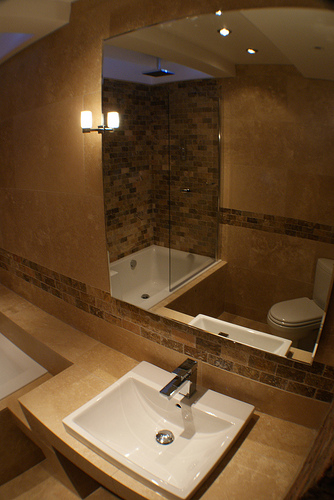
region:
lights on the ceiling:
[184, 12, 271, 68]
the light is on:
[54, 88, 143, 146]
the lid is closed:
[257, 277, 317, 337]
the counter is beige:
[233, 417, 285, 485]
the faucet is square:
[142, 344, 208, 419]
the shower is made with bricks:
[110, 83, 221, 250]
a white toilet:
[264, 254, 332, 344]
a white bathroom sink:
[62, 359, 260, 498]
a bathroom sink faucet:
[153, 354, 201, 406]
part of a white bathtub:
[106, 237, 203, 311]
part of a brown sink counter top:
[207, 410, 310, 498]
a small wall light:
[78, 105, 97, 136]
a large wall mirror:
[85, 0, 331, 362]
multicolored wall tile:
[0, 247, 144, 336]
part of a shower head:
[141, 60, 173, 80]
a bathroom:
[0, 26, 331, 496]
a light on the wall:
[79, 109, 98, 131]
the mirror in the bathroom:
[103, 34, 331, 388]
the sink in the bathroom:
[66, 360, 250, 498]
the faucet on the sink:
[155, 361, 204, 402]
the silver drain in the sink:
[155, 425, 174, 445]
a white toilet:
[265, 254, 329, 334]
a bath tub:
[109, 236, 207, 308]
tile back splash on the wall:
[8, 254, 112, 319]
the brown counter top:
[72, 338, 116, 383]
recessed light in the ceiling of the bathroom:
[243, 46, 259, 56]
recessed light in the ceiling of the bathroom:
[217, 25, 231, 37]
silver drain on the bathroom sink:
[152, 425, 173, 444]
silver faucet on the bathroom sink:
[151, 355, 203, 404]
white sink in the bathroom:
[54, 352, 260, 498]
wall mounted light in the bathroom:
[76, 105, 100, 139]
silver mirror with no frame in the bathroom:
[91, 1, 331, 373]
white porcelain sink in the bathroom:
[49, 350, 268, 498]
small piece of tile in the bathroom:
[139, 323, 185, 355]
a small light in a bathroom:
[79, 106, 97, 133]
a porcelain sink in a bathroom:
[60, 354, 250, 493]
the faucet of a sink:
[156, 355, 196, 399]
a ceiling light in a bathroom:
[215, 25, 226, 33]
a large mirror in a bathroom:
[101, 7, 328, 361]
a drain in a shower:
[139, 290, 145, 295]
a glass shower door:
[163, 92, 219, 283]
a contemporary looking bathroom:
[3, 1, 333, 498]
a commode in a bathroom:
[265, 255, 332, 343]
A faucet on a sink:
[158, 355, 199, 401]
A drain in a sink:
[155, 426, 175, 445]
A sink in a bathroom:
[61, 357, 255, 498]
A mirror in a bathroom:
[101, 5, 329, 366]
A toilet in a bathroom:
[267, 254, 330, 343]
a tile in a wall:
[82, 284, 115, 304]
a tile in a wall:
[76, 298, 88, 315]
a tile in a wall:
[89, 304, 102, 317]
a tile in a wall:
[102, 309, 119, 324]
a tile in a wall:
[117, 317, 139, 333]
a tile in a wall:
[138, 326, 158, 343]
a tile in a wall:
[161, 333, 182, 353]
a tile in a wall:
[182, 344, 204, 360]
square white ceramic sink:
[62, 351, 265, 492]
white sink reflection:
[188, 306, 296, 358]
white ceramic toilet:
[264, 287, 329, 338]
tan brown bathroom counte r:
[29, 318, 316, 497]